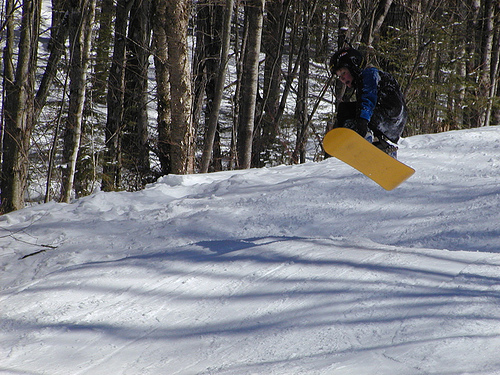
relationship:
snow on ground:
[0, 269, 500, 375] [9, 208, 496, 368]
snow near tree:
[0, 269, 500, 375] [238, 2, 263, 160]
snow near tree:
[0, 269, 500, 375] [164, 6, 196, 167]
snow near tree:
[0, 269, 500, 375] [294, 14, 311, 156]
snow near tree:
[0, 269, 500, 375] [65, 11, 90, 196]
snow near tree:
[0, 269, 500, 375] [5, 3, 25, 204]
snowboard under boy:
[326, 120, 468, 212] [319, 47, 408, 160]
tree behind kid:
[236, 0, 263, 168] [329, 46, 409, 159]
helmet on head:
[328, 47, 363, 74] [328, 46, 363, 86]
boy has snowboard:
[319, 47, 408, 160] [322, 128, 414, 191]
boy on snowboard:
[319, 40, 412, 142] [316, 122, 417, 189]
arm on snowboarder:
[358, 65, 379, 137] [327, 47, 407, 157]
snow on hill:
[0, 269, 500, 375] [4, 2, 497, 374]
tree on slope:
[159, 2, 191, 174] [6, 125, 495, 374]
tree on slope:
[235, 0, 267, 175] [6, 125, 495, 374]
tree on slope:
[121, 4, 152, 191] [6, 125, 495, 374]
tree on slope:
[62, 2, 89, 201] [6, 125, 495, 374]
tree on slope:
[200, 4, 235, 174] [6, 125, 495, 374]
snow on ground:
[105, 211, 467, 363] [1, 136, 498, 368]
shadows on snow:
[72, 180, 457, 363] [21, 175, 498, 373]